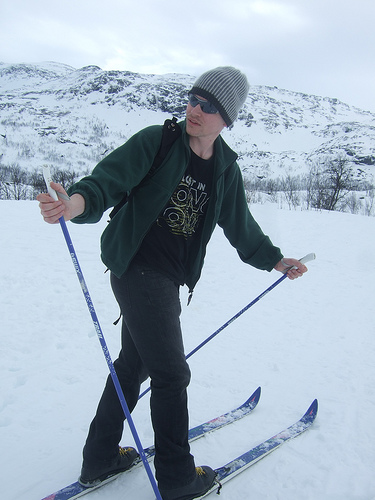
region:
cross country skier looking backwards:
[25, 55, 325, 494]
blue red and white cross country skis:
[27, 380, 328, 499]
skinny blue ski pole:
[43, 212, 166, 497]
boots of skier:
[72, 431, 223, 498]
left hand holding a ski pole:
[269, 248, 312, 287]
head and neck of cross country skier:
[175, 57, 253, 161]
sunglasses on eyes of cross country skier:
[182, 88, 229, 118]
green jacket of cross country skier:
[54, 113, 289, 304]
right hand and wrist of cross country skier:
[25, 167, 101, 230]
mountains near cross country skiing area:
[4, 56, 371, 221]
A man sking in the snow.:
[34, 64, 319, 499]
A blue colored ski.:
[194, 394, 319, 499]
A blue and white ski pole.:
[41, 162, 163, 497]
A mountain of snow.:
[0, 61, 374, 220]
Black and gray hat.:
[187, 66, 251, 128]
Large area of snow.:
[179, 209, 373, 498]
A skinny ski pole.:
[185, 251, 316, 360]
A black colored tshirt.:
[133, 145, 225, 286]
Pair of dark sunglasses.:
[184, 91, 219, 113]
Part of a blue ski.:
[188, 386, 263, 442]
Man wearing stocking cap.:
[198, 51, 253, 121]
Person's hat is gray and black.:
[192, 71, 265, 136]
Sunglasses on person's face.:
[181, 89, 231, 130]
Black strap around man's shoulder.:
[141, 117, 180, 190]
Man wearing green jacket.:
[124, 130, 224, 238]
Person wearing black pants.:
[139, 358, 203, 486]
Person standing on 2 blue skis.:
[91, 423, 230, 491]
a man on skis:
[31, 63, 316, 498]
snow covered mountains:
[0, 60, 370, 182]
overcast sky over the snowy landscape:
[0, 0, 370, 105]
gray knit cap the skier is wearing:
[185, 62, 246, 122]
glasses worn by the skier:
[186, 90, 222, 112]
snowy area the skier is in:
[0, 199, 372, 494]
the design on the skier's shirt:
[159, 172, 204, 233]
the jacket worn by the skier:
[63, 116, 276, 296]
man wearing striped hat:
[215, 73, 232, 95]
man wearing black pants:
[159, 322, 173, 359]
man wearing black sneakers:
[149, 473, 225, 496]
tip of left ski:
[297, 389, 325, 426]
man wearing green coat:
[121, 154, 135, 175]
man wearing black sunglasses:
[184, 93, 220, 112]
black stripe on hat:
[201, 91, 212, 101]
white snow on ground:
[275, 323, 321, 349]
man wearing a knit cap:
[184, 57, 252, 133]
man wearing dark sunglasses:
[184, 91, 218, 118]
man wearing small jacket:
[60, 113, 291, 287]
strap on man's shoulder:
[99, 104, 182, 227]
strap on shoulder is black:
[99, 109, 186, 216]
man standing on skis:
[37, 54, 310, 498]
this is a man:
[39, 47, 283, 438]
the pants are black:
[87, 279, 192, 445]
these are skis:
[184, 387, 352, 497]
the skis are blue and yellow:
[205, 369, 337, 472]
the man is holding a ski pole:
[35, 189, 194, 384]